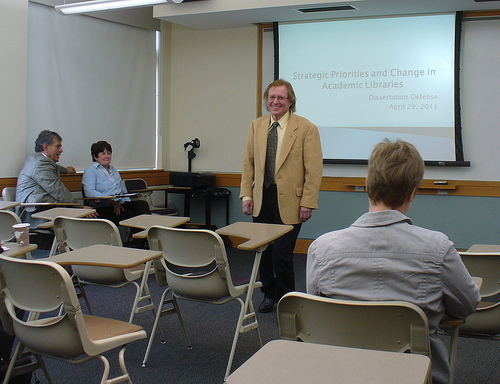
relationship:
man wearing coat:
[231, 75, 328, 322] [233, 110, 327, 230]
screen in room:
[276, 12, 464, 165] [58, 41, 460, 344]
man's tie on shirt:
[264, 120, 279, 182] [254, 124, 311, 154]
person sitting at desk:
[82, 137, 155, 241] [3, 238, 166, 382]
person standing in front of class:
[242, 80, 312, 311] [15, 1, 489, 367]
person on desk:
[280, 129, 483, 353] [293, 213, 483, 359]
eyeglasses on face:
[265, 95, 291, 104] [264, 89, 302, 124]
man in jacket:
[231, 75, 328, 322] [236, 112, 323, 223]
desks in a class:
[0, 196, 498, 381] [15, 1, 489, 367]